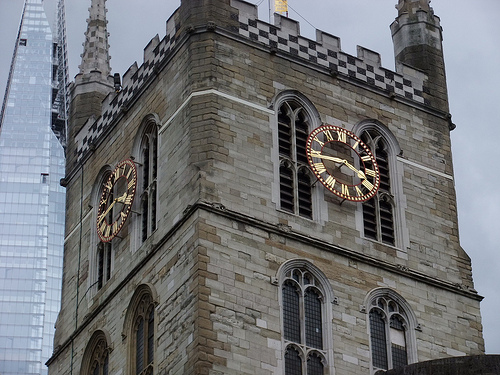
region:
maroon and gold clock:
[298, 113, 384, 209]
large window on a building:
[271, 250, 333, 374]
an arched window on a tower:
[270, 251, 334, 369]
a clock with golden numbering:
[299, 118, 384, 216]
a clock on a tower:
[86, 156, 144, 248]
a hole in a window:
[383, 321, 410, 353]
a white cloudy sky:
[456, 6, 499, 195]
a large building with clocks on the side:
[36, 0, 490, 374]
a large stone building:
[36, 1, 491, 373]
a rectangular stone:
[230, 134, 248, 149]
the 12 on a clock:
[333, 126, 349, 143]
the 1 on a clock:
[350, 137, 359, 150]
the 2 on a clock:
[355, 151, 375, 165]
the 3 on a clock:
[362, 165, 379, 178]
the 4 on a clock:
[362, 178, 375, 193]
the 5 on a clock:
[353, 184, 365, 198]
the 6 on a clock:
[339, 180, 351, 199]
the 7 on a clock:
[323, 173, 337, 192]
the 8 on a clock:
[308, 158, 327, 177]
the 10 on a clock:
[310, 133, 325, 148]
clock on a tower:
[292, 116, 394, 212]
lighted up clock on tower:
[305, 88, 387, 227]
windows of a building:
[268, 234, 423, 368]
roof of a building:
[228, 11, 463, 133]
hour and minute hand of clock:
[301, 145, 371, 180]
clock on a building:
[81, 148, 148, 237]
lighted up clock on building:
[87, 156, 151, 248]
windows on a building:
[125, 110, 167, 257]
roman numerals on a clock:
[300, 107, 392, 209]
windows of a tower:
[275, 253, 332, 346]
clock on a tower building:
[295, 118, 391, 207]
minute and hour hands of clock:
[315, 144, 368, 186]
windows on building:
[256, 234, 413, 374]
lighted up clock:
[292, 116, 394, 205]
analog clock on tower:
[85, 153, 146, 236]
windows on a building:
[264, 82, 335, 237]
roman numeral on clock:
[296, 107, 397, 212]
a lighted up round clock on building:
[87, 152, 154, 249]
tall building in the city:
[15, 5, 81, 275]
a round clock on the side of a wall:
[306, 124, 381, 202]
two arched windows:
[271, 89, 404, 251]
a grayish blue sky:
[0, 4, 498, 354]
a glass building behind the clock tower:
[0, 0, 65, 372]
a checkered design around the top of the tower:
[71, 14, 425, 167]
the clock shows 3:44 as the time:
[303, 125, 380, 202]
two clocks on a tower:
[95, 123, 380, 245]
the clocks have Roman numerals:
[96, 126, 381, 246]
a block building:
[45, 2, 483, 374]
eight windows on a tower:
[78, 93, 418, 373]